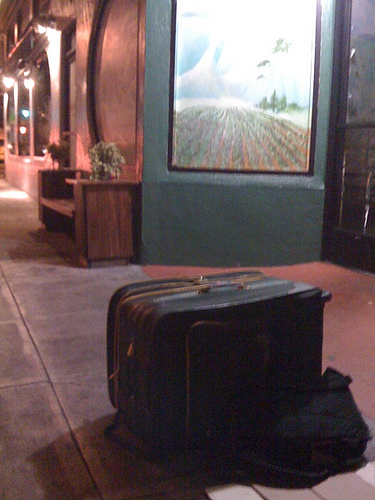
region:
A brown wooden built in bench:
[28, 157, 142, 273]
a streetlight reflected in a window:
[2, 72, 36, 91]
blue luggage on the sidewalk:
[105, 270, 371, 486]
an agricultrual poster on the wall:
[164, 1, 325, 178]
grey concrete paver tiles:
[3, 277, 107, 401]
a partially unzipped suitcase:
[94, 276, 248, 458]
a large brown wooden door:
[317, 21, 373, 270]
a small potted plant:
[87, 140, 122, 183]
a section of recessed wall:
[76, 0, 145, 171]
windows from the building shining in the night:
[0, 39, 55, 165]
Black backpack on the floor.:
[216, 367, 371, 488]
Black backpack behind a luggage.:
[213, 365, 372, 489]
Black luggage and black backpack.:
[102, 267, 370, 487]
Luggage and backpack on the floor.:
[105, 268, 373, 487]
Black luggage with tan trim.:
[105, 266, 332, 455]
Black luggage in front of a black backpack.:
[105, 267, 330, 452]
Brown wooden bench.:
[35, 167, 139, 268]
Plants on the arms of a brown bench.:
[30, 139, 124, 180]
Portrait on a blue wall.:
[166, 1, 321, 176]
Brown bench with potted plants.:
[35, 137, 136, 266]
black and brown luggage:
[110, 244, 345, 440]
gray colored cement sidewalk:
[10, 305, 93, 477]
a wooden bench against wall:
[50, 157, 139, 282]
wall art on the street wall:
[174, 4, 319, 185]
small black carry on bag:
[250, 370, 372, 487]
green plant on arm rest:
[77, 134, 145, 210]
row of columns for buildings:
[3, 52, 87, 142]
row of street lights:
[4, 61, 84, 161]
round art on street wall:
[85, 47, 150, 128]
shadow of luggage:
[30, 418, 161, 498]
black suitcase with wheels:
[100, 262, 337, 450]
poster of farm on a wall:
[164, 1, 326, 177]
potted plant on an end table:
[83, 136, 133, 189]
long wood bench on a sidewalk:
[34, 159, 136, 272]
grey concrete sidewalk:
[8, 269, 107, 485]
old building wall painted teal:
[144, 173, 287, 253]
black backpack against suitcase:
[228, 366, 366, 481]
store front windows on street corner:
[5, 21, 68, 194]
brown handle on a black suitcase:
[193, 278, 253, 297]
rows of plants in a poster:
[190, 110, 247, 166]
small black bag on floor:
[215, 366, 373, 489]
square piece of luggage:
[102, 269, 333, 444]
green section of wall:
[140, 3, 340, 269]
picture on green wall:
[164, 0, 323, 173]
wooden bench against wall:
[30, 158, 138, 267]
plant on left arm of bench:
[87, 140, 123, 180]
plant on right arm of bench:
[44, 137, 68, 164]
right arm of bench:
[37, 166, 72, 199]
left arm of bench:
[67, 173, 139, 210]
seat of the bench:
[44, 188, 75, 219]